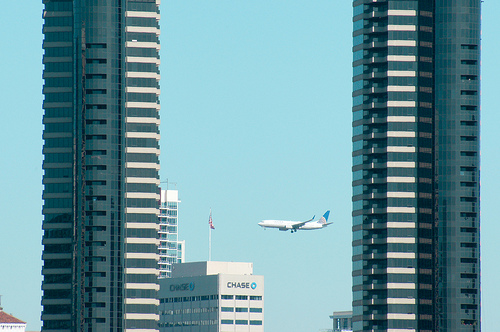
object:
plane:
[258, 210, 333, 232]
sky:
[1, 0, 500, 332]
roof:
[1, 308, 22, 321]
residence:
[0, 321, 25, 329]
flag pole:
[208, 211, 215, 260]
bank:
[156, 261, 263, 330]